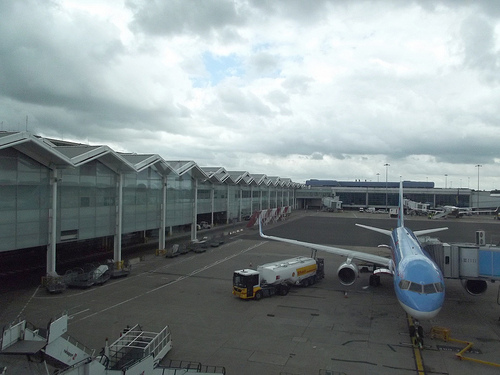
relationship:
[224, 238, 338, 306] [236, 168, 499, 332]
fuel goes to airplane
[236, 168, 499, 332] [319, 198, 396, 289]
airplane has cockpit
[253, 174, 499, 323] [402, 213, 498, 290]
airplane has passenger tunnel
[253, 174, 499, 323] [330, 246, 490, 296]
airplane has turbine engines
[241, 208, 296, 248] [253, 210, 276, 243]
tip curves upwards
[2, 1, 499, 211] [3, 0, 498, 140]
sky has overcast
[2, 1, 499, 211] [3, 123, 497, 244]
sky above airport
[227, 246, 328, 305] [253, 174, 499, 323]
fuel next to airplane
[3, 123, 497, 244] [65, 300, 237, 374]
airport has staircase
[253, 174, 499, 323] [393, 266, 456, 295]
airplane has front windows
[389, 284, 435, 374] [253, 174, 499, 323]
line under airplane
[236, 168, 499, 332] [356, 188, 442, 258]
airplane has tail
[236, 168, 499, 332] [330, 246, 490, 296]
airplane has engine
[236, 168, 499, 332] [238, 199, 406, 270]
airplane has wing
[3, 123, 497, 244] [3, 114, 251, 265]
building to left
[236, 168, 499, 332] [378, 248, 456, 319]
airplane has cockpit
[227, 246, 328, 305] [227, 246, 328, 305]
fuel has fuel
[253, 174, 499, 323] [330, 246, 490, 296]
airplane has engine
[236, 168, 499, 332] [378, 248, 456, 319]
airplane has windows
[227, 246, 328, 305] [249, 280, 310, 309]
fuel has wheels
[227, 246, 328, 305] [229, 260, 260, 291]
fuel has windshields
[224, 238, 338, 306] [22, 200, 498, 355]
tanker on tarmac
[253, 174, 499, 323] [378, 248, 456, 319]
airplane has cockpit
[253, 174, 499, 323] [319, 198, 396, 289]
airplane has cockpit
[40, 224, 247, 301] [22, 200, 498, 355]
equiptment on tarmac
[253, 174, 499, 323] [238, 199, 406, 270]
airplane has right wing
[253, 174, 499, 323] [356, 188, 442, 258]
airplane has tail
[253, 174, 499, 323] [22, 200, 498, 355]
airplane parked on tarmac